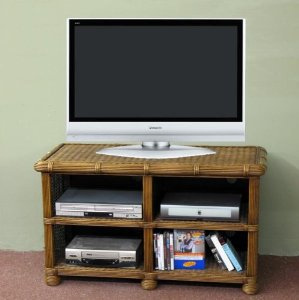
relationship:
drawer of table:
[65, 234, 141, 266] [30, 137, 288, 299]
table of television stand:
[30, 137, 288, 299] [28, 143, 268, 297]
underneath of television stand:
[53, 276, 249, 290] [28, 143, 268, 297]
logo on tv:
[149, 126, 163, 129] [64, 16, 245, 159]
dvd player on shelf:
[159, 193, 244, 221] [44, 201, 263, 242]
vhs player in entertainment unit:
[64, 233, 143, 271] [37, 140, 269, 289]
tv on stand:
[58, 15, 253, 142] [95, 140, 216, 157]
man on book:
[180, 230, 192, 252] [170, 233, 206, 260]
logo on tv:
[149, 124, 163, 129] [64, 16, 245, 159]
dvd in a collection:
[170, 233, 177, 272] [153, 229, 243, 271]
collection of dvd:
[153, 229, 243, 271] [170, 233, 177, 272]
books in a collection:
[153, 229, 246, 277] [147, 234, 235, 278]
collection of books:
[147, 234, 235, 278] [153, 229, 246, 277]